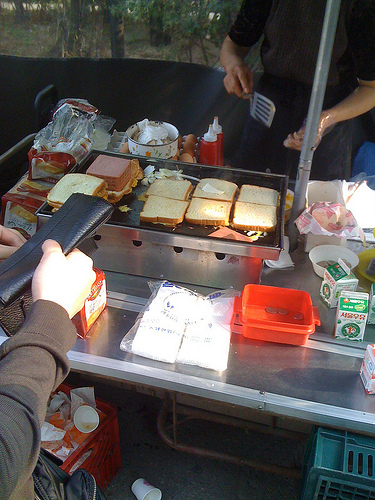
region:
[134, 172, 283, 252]
Six sandwiches on a black grill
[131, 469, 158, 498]
A small white cup thrown on the ground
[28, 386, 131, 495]
A small orange milk crate functioning as a trash can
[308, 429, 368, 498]
A green crate under the table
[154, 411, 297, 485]
A rusted metal bar under the table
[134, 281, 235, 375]
A plastic package of napkins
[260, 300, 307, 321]
Three quarters in the tip box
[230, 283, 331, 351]
A small orange tip box on the table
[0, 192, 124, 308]
A small black wallet in the hands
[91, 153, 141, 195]
A stack of deli meat for the sandwiches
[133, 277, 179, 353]
A white sealed serveitte clothes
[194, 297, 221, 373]
A white sealed serveitte clothes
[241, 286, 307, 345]
An Orange coin dish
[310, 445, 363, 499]
A plastic green creat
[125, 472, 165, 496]
A empty plactic disposable cup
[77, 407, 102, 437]
A empty plactic disposable cup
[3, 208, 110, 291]
A black leather wallet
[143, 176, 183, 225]
A delicious looking toasted bread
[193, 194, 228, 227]
A delicious looking toasted bread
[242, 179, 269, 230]
A delicious looking toasted bread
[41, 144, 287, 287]
a rectangular grill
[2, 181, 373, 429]
a sturdy-looking metal table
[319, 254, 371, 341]
two small white, green, and red cartons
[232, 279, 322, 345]
coins in an orange container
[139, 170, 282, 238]
slices of bread on grill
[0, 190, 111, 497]
a person holding a long wallet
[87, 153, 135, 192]
pink slices of meat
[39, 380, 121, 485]
rubbish in an orange milk crate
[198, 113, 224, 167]
red squeezable bottles with white tops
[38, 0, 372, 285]
person standing behind grill holding a spatula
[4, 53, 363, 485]
People making sandwiches on a grill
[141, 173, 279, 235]
Six sandwiches being cooked on a grill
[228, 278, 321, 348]
A small orange tip box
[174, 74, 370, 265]
A man cooking sandwiches with ham and cheese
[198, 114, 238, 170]
Two bottles of ketchup with white lids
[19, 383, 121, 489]
An orange milk crate serving as a trash bin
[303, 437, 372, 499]
A green crate shoved under the table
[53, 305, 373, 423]
A grey table underneath the grill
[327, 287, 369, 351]
A green and white carton of milk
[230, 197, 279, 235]
sandwich on a grill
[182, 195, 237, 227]
sandwich on a grill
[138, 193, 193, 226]
sandwich on a grill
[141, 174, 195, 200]
sandwich on a grill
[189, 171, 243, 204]
sandwich on a grill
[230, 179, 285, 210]
sandwich on a grill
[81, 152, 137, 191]
large stack of meat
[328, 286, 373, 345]
white and green container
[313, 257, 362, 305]
white and green container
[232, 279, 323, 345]
plastic bin with change inside